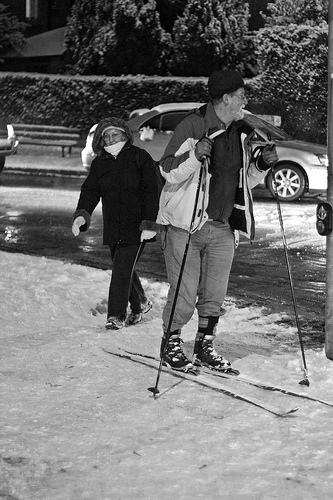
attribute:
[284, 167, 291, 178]
spoke — white 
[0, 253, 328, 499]
snow — clods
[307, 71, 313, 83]
leaf — frosty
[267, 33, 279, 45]
leaf — frosty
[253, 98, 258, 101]
leaf — frosty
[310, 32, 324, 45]
leaf — frosty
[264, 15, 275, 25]
leaf — frosty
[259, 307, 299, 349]
snow — clods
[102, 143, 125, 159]
mask — white, paper, face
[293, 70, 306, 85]
leaf — frosty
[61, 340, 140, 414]
snow — clods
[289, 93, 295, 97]
leaf — frosty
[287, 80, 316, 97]
leaf — frosty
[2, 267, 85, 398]
snow — clods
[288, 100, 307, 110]
leaf — frosty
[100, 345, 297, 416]
ski — black